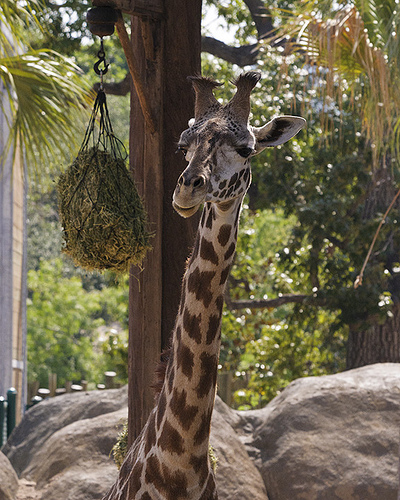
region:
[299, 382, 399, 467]
the rocks are grey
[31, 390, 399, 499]
the rocks are big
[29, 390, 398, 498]
the rocks are two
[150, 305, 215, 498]
the giraffe has spots on the neck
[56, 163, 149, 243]
there is grass hay in the air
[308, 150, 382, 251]
the trees are in the background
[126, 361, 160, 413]
the pole is wooden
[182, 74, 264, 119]
the giraffe has two horns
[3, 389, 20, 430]
the fence is blue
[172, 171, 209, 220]
the giraffe has two nostrils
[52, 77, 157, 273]
a bundle of hay in a black net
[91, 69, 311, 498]
a giraffe with a long neck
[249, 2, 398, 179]
the palm has dried leaves on it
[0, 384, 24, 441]
green metal fence posts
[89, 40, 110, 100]
black hook holding net with hay in it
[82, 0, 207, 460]
wooden support post behind giraffe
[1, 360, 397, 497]
grey rocks behind giraffe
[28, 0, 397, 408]
green trees behind giraffe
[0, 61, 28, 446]
brown brick building next to giraffe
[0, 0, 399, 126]
the sky is bright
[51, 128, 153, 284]
A hanging bag of food.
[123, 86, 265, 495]
A giraffe looking at a bag of food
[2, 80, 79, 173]
A frond from a palm tree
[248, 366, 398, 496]
A large grey stone on the ground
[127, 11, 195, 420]
A long wooden pole.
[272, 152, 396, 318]
many leafy trees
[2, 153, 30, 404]
a brick wall of the building.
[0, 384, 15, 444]
a metal fence with green poles.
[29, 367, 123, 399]
a wooden fence behind the rocks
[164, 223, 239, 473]
a very long giraffe neck.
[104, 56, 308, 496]
A giraffe standing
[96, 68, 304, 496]
A giraffe looking at food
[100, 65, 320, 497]
Brown and white giraffe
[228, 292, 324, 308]
Branch on tree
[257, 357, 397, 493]
Gray and tan boulder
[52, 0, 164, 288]
Green giraffe food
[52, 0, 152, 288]
Giraffe food hanging from tree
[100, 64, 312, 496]
One giraffe staring at food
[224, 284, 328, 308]
Brown branch on tree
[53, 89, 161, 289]
Black net holding giraffe food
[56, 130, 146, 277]
a net full of food for the giraffe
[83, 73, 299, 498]
a long tall giraffe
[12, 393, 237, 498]
a big rock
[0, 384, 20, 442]
a green fence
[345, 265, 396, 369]
a tall tree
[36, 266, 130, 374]
a lot of green leaves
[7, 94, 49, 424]
a home for the giraffe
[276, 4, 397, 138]
a dried out palm frond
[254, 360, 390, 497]
another large rock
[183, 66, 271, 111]
giraffe ears